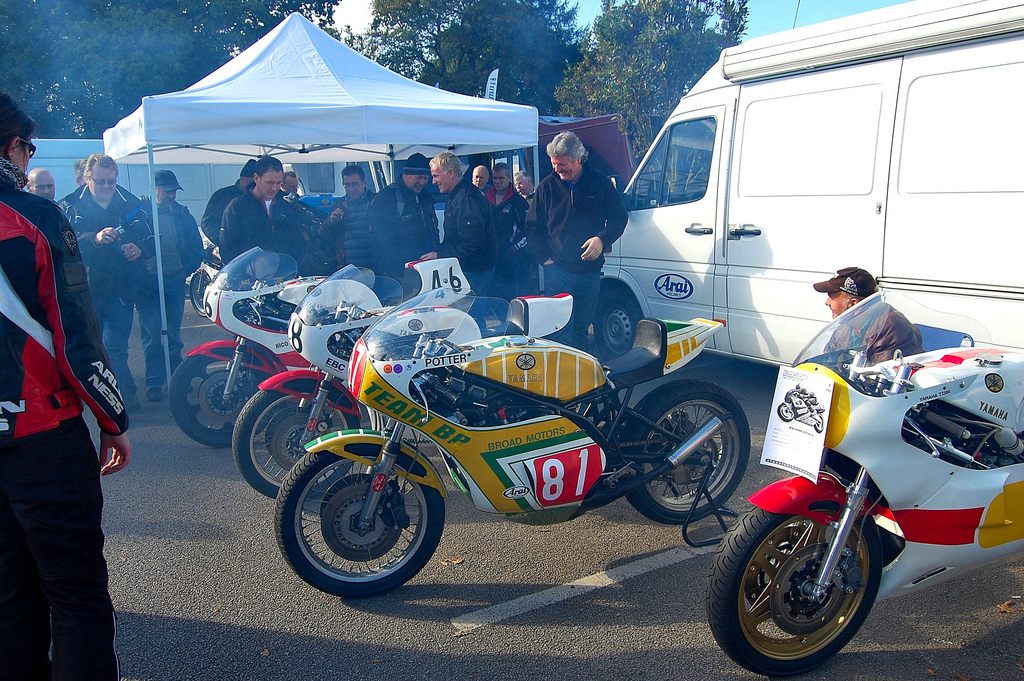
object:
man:
[523, 128, 632, 354]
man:
[419, 151, 501, 338]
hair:
[428, 151, 465, 180]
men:
[133, 167, 206, 403]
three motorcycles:
[165, 240, 757, 602]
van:
[584, 0, 1021, 370]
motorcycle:
[701, 342, 1024, 679]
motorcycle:
[231, 262, 574, 501]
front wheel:
[269, 441, 450, 599]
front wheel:
[228, 378, 363, 501]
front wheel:
[165, 345, 278, 453]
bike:
[163, 242, 523, 449]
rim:
[735, 509, 871, 662]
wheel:
[703, 502, 886, 677]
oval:
[652, 272, 697, 302]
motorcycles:
[701, 342, 1024, 679]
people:
[0, 119, 633, 417]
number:
[540, 456, 567, 502]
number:
[572, 447, 590, 498]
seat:
[597, 316, 666, 392]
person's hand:
[95, 421, 133, 476]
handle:
[684, 222, 714, 235]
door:
[595, 80, 747, 356]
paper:
[756, 361, 838, 487]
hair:
[544, 128, 589, 163]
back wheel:
[621, 374, 754, 526]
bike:
[271, 284, 755, 599]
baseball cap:
[812, 265, 877, 297]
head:
[812, 265, 881, 320]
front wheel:
[699, 489, 891, 681]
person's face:
[2, 123, 37, 183]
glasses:
[8, 139, 39, 159]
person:
[216, 154, 304, 291]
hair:
[253, 155, 286, 178]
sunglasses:
[91, 177, 119, 186]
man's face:
[87, 162, 119, 199]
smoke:
[17, 32, 324, 382]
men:
[216, 153, 308, 295]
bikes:
[197, 217, 679, 486]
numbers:
[574, 449, 591, 498]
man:
[812, 266, 927, 368]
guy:
[0, 88, 139, 681]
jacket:
[0, 187, 133, 442]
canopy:
[101, 9, 540, 166]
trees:
[28, 70, 40, 106]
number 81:
[541, 447, 596, 502]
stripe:
[448, 546, 695, 638]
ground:
[0, 441, 1024, 677]